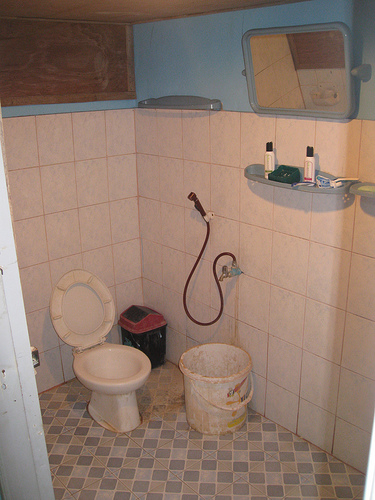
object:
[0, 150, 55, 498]
bathroom door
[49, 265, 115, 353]
lid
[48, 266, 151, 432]
toilet bowl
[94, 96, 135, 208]
wall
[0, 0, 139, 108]
wooden panel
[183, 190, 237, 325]
fountain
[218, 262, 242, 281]
faucet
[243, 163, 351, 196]
shelf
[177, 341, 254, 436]
bucket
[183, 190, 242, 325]
shower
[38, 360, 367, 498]
ground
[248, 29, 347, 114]
mirror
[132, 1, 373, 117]
wall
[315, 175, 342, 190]
toothpaste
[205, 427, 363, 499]
floor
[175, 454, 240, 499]
tile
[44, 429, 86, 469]
tile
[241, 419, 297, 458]
tile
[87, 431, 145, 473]
tile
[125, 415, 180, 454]
tile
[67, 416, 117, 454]
tiles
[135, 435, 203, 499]
floor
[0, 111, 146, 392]
wall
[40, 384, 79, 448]
floor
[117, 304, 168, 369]
garbage bin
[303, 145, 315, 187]
toiletrie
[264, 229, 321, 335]
wall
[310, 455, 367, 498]
tile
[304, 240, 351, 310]
tiles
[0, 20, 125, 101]
opening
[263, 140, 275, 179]
toiletries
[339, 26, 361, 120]
trim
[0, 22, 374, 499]
toilet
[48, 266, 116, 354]
seat up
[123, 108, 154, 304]
corner